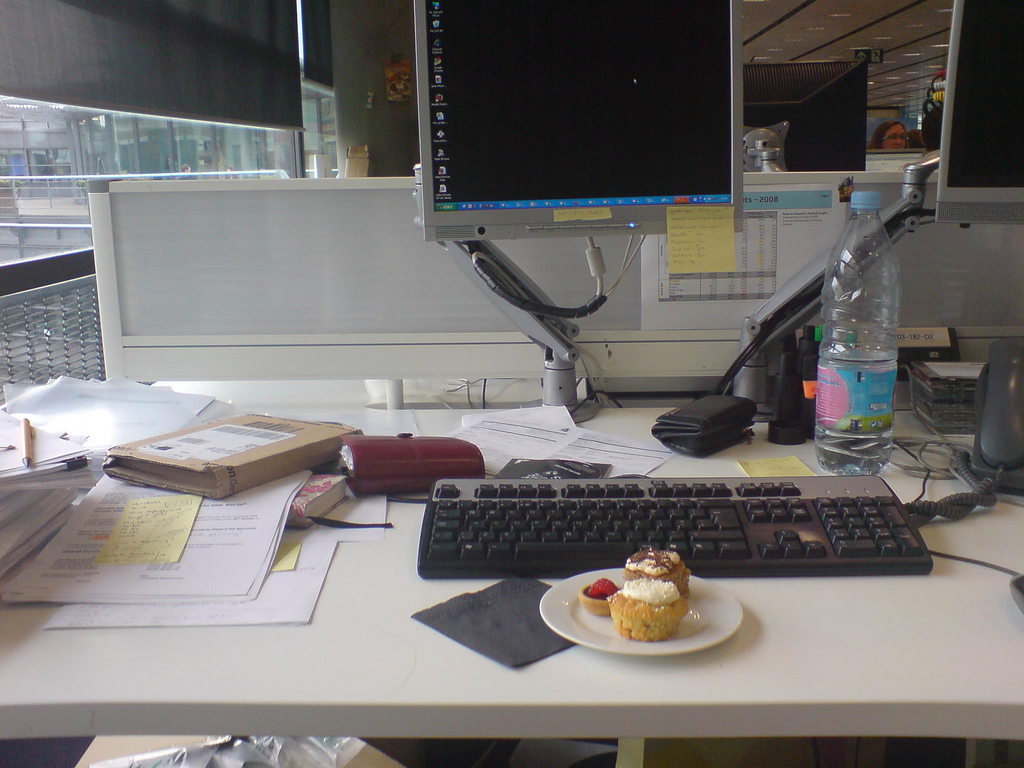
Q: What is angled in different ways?
A: The computer screens.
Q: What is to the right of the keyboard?
A: A black phone.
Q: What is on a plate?
A: Food.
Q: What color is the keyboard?
A: Black.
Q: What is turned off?
A: A screen.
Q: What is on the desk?
A: Some treats.